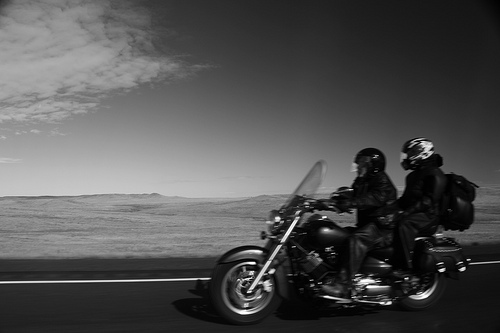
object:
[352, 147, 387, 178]
helmet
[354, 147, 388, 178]
head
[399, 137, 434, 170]
helmet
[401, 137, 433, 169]
head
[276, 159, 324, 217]
windshield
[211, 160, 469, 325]
bike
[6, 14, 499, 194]
sky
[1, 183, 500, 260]
plains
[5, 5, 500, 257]
background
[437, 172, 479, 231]
backpack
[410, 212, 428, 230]
black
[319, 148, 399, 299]
driver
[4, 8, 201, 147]
cloud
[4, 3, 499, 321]
picture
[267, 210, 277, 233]
headlight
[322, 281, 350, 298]
boots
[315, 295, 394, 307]
pipe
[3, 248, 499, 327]
pavement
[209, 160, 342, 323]
front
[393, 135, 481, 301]
back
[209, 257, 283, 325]
front wheel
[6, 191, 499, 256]
mountain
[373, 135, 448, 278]
passenger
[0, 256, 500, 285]
line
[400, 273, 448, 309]
back wheel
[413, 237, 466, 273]
saddle bag